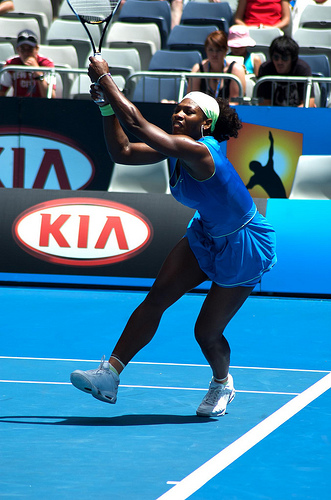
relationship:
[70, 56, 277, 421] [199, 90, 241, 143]
woman has hair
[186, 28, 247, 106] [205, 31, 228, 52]
spectator has hair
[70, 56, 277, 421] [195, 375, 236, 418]
woman has foot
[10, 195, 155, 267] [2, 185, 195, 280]
sign on side of black wall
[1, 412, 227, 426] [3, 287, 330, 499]
shadow on top of ground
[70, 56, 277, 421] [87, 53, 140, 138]
woman has hand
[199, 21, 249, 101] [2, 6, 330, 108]
spectator in stands